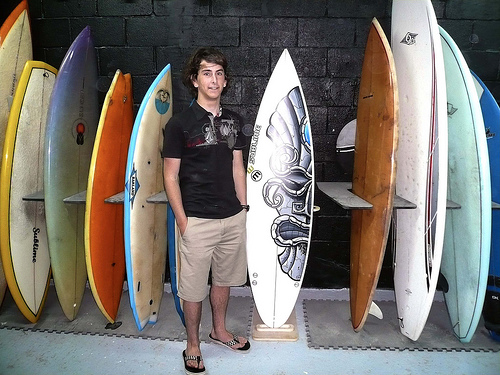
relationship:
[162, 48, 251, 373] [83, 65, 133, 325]
boy standing next to surfboard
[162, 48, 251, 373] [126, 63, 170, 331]
boy standing next to board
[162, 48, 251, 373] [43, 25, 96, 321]
boy standing next to board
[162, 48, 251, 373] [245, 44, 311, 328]
boy standing next to surfboard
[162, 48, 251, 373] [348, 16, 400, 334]
boy standing next to surfboard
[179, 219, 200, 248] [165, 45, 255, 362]
hand belonging to man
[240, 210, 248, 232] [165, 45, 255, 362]
hand belonging to man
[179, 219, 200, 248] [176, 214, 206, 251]
hand stuck into pocket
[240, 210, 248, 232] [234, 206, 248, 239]
hand stuck into pocket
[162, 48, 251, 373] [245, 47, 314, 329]
boy standing next to surf board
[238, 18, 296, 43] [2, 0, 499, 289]
block holding up wall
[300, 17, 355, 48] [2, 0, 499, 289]
block holding up wall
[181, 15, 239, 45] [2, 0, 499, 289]
block holding up wall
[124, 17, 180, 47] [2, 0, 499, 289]
block holding up wall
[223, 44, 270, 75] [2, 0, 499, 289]
block holding up wall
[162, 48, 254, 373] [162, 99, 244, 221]
boy wearing shirt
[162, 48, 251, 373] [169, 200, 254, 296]
boy wearing tan shorts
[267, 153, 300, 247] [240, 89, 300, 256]
picture airbrushed on surfboard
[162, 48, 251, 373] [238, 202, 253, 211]
boy wearing watch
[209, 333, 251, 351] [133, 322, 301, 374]
flip flop on feet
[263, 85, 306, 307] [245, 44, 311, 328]
surface of surfboard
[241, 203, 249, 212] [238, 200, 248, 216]
watch on wrist